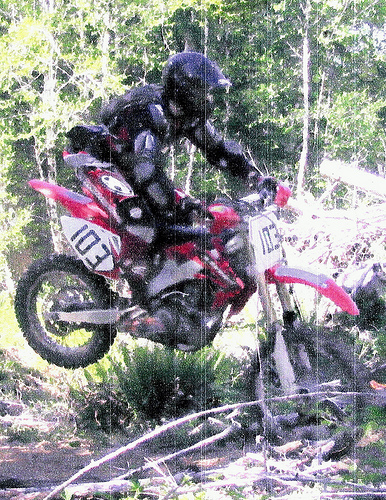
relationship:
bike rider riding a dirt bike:
[65, 49, 279, 333] [44, 156, 321, 418]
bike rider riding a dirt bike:
[65, 49, 279, 333] [13, 178, 370, 461]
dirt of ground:
[0, 426, 242, 486] [0, 397, 384, 497]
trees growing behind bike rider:
[0, 0, 384, 294] [61, 45, 292, 346]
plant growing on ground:
[87, 330, 240, 414] [2, 291, 373, 494]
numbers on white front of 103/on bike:
[235, 212, 304, 273] [14, 149, 370, 461]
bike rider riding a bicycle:
[65, 49, 279, 333] [15, 145, 369, 460]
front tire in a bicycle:
[244, 325, 373, 457] [16, 145, 382, 475]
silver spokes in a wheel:
[29, 291, 49, 336] [13, 254, 122, 366]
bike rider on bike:
[65, 49, 279, 333] [15, 153, 367, 464]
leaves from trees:
[3, 2, 384, 150] [0, 1, 385, 260]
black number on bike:
[70, 224, 114, 275] [19, 127, 376, 455]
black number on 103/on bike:
[63, 225, 114, 275] [59, 214, 119, 269]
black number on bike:
[70, 224, 114, 275] [15, 153, 367, 464]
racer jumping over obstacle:
[71, 44, 285, 271] [69, 382, 310, 474]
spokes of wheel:
[266, 349, 348, 436] [245, 329, 367, 454]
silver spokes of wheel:
[29, 308, 54, 325] [18, 250, 112, 367]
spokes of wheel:
[266, 377, 346, 395] [242, 309, 385, 487]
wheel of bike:
[13, 254, 122, 366] [19, 127, 376, 455]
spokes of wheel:
[38, 277, 65, 294] [13, 254, 122, 366]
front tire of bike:
[244, 325, 373, 457] [13, 51, 368, 458]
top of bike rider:
[90, 83, 252, 212] [65, 49, 279, 333]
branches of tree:
[285, 40, 299, 82] [235, 18, 385, 232]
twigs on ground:
[208, 442, 310, 492] [2, 291, 373, 494]